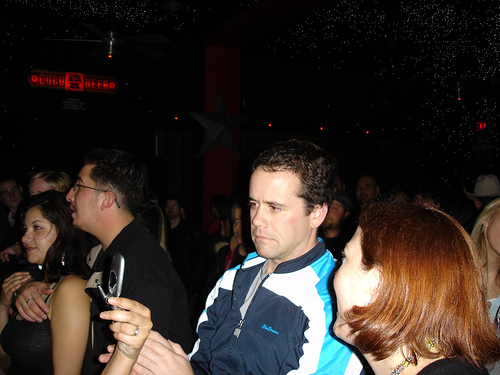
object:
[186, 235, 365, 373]
coat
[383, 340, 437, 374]
necklace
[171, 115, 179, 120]
star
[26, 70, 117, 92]
sign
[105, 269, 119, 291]
black circle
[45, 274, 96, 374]
arm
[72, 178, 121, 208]
glasses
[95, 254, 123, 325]
flip phone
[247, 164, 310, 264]
face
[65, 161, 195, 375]
man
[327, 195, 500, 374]
woman